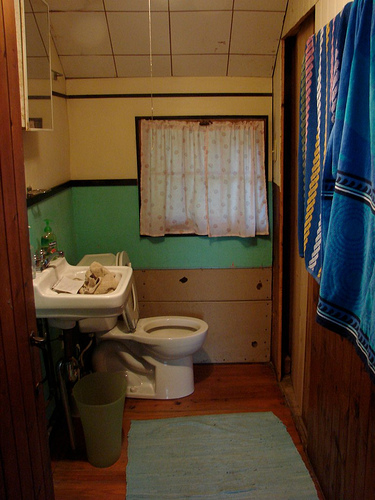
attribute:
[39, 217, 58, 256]
soap — hand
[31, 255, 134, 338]
sink — white, porcelain, bathroom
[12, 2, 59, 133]
cabinet — medicine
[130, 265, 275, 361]
cabinet — medicine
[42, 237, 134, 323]
sink — bathroom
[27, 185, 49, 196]
dish — soap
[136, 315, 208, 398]
white bowl — toilet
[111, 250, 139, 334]
toilet lid — in up position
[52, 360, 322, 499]
boards — knotty, wooden, floor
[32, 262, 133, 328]
sink — white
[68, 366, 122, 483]
garbage can — plastic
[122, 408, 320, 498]
floor rug — blue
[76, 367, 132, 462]
trash can — plastic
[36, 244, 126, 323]
sink — bathroom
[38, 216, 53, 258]
bottle — plastic, soap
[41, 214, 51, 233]
lid — green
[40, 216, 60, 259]
soap — liquid , hand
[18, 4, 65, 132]
cabinet — medicine